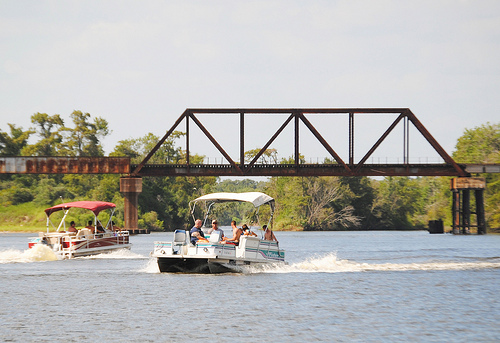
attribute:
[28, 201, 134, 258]
pontoon — red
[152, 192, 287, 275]
boat — blue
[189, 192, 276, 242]
canopy — white, grey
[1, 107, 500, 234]
bridge — rusty, secure, tresle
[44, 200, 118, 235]
canopy — red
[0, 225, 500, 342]
water — muddy, white, calm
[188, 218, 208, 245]
shirt — blue, sitting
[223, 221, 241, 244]
man — shirtless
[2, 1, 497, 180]
sky — gray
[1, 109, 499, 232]
foliage — green